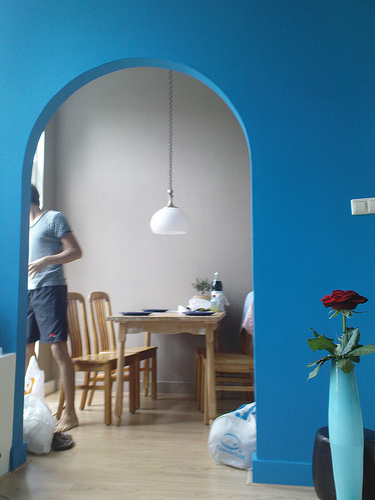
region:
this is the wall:
[238, 19, 263, 43]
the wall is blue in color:
[272, 94, 310, 139]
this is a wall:
[98, 176, 122, 209]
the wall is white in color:
[98, 202, 128, 248]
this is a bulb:
[141, 183, 190, 234]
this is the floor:
[133, 446, 183, 491]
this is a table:
[111, 309, 215, 421]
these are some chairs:
[70, 290, 156, 403]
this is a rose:
[318, 285, 369, 349]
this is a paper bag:
[216, 404, 254, 464]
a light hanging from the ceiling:
[145, 187, 197, 237]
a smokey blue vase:
[322, 353, 365, 499]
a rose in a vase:
[306, 289, 374, 380]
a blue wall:
[1, 0, 373, 485]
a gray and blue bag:
[207, 399, 256, 473]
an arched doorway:
[12, 54, 260, 482]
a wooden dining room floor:
[0, 386, 319, 499]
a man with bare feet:
[24, 176, 95, 432]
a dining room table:
[102, 297, 235, 429]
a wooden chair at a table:
[52, 291, 136, 421]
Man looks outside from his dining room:
[3, 47, 318, 483]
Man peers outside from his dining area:
[0, 48, 370, 493]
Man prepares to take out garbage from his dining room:
[12, 48, 368, 494]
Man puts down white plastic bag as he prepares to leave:
[6, 49, 366, 490]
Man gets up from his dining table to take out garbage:
[5, 50, 275, 494]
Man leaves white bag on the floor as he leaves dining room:
[3, 47, 295, 489]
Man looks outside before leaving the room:
[1, 52, 301, 494]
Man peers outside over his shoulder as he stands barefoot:
[2, 49, 303, 495]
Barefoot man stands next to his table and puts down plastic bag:
[2, 45, 284, 495]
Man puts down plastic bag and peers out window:
[5, 45, 306, 492]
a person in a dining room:
[26, 181, 80, 429]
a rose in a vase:
[307, 283, 373, 497]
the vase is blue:
[316, 356, 371, 497]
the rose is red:
[315, 281, 370, 321]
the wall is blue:
[2, 3, 371, 479]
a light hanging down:
[147, 63, 195, 247]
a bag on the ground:
[8, 350, 59, 452]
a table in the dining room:
[105, 295, 221, 430]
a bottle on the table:
[209, 268, 224, 307]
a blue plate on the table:
[116, 305, 154, 318]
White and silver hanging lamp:
[144, 67, 195, 234]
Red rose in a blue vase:
[302, 285, 369, 495]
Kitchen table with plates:
[102, 301, 225, 422]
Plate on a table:
[113, 304, 152, 314]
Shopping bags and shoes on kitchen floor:
[19, 350, 72, 455]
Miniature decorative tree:
[188, 271, 209, 294]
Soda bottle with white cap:
[206, 270, 221, 300]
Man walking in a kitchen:
[21, 171, 247, 427]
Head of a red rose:
[315, 285, 367, 317]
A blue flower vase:
[324, 358, 363, 497]